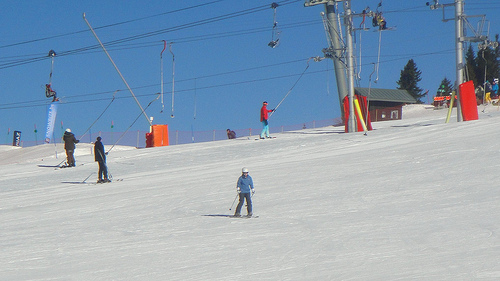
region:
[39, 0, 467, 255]
a busy ski slope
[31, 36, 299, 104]
the ski life is running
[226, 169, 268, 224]
this skier is wearing a blue jacket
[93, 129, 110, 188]
this skier appears to be in all black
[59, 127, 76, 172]
this skier has on a white helmet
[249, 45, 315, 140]
this man is working on the ski lift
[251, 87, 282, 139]
he is wearing a red jacket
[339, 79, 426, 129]
a small building in the back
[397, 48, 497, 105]
evergreen trees in the distance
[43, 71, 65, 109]
skiers on the lift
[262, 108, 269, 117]
the coat is red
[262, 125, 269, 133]
the pants are light blue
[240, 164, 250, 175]
the helmet is white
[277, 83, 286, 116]
the pole is gray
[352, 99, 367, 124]
the pole is yellow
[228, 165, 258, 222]
the persons on the ski's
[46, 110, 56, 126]
the sign is blue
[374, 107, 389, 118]
the building is brown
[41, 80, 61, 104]
the person is on the lift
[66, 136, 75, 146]
the coat is black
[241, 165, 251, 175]
head of a person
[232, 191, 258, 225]
legs of a person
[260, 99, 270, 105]
head of a person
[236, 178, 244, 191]
arm of a person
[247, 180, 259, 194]
arm of a person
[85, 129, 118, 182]
person on a snow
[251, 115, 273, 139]
leg of a person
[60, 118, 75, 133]
head of a person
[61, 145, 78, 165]
legs of a person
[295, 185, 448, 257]
a plain snowy field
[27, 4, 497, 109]
people riding on a ski lift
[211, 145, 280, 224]
a person sking on snow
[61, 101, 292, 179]
people holding up a pole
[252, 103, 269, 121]
a person wearing a red jacket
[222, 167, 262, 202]
a person wearing a blue jacket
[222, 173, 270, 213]
a person standing on snow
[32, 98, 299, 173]
people standing on snow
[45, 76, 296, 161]
people standing near a ski life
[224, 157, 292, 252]
a person sking down a slope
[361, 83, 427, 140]
a hut located on top of a snow slope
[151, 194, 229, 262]
Snow in the mountain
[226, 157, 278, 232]
A person skiing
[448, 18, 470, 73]
A metal pole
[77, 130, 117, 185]
Black skating clothes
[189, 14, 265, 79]
Clouds in the photo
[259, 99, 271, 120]
Red jacket in the photo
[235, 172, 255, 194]
Blue jacket in the photo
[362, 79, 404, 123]
A house in the photo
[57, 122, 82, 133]
A white helmet in the photo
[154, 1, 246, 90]
Cables in the photo